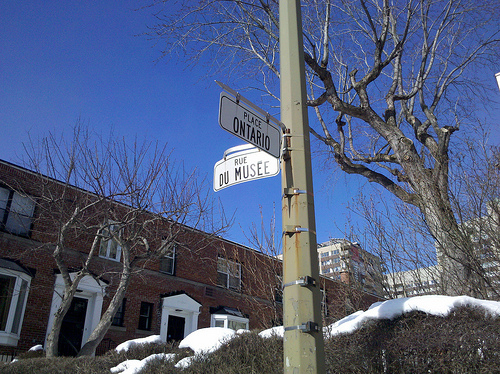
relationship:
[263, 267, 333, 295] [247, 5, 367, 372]
metallic braces on pole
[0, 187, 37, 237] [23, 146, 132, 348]
window on building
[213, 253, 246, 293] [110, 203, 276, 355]
window on building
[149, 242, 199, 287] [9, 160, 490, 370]
window on building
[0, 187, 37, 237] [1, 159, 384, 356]
window on building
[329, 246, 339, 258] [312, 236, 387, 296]
window on building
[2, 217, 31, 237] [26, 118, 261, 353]
window on building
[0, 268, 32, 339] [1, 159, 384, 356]
window on building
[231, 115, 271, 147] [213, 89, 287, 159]
lettering on sign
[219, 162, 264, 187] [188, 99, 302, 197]
lettering on sign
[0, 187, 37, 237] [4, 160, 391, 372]
window on building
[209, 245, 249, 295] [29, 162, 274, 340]
window on building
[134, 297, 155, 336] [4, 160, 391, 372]
window on building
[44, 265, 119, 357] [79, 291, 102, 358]
door with frame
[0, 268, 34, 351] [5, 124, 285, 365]
window on building